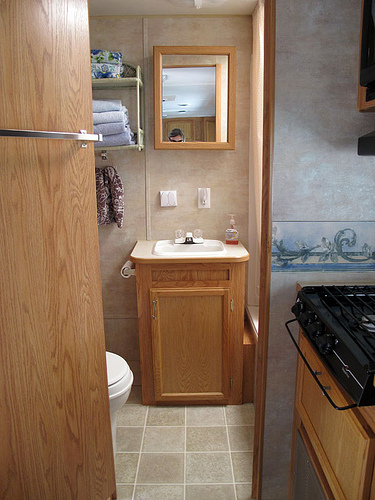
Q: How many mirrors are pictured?
A: One.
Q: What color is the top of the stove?
A: Black.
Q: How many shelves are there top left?
A: Two.